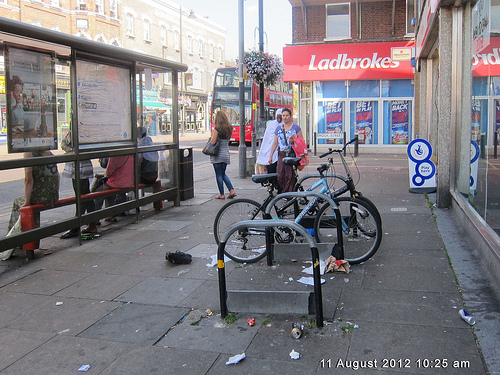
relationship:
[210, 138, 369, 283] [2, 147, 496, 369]
bicycle rack on sidewalk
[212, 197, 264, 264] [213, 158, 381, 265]
wheel on bicycle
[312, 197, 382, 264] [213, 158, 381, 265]
wheel on bicycle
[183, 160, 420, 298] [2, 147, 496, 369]
bicycle on sidewalk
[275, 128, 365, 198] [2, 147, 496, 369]
bicycle on sidewalk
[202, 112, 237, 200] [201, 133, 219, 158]
woman holding bag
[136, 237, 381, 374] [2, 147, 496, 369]
trash on sidewalk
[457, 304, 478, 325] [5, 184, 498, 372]
can on ground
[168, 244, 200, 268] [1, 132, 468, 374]
trash on sidewalk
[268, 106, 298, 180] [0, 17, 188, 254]
people at bus stop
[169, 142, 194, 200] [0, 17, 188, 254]
trash can at bus stop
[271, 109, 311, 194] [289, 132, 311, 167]
woman with sweater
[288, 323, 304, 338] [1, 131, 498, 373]
can on concrete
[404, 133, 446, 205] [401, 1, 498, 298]
sign on building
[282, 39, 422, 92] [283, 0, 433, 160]
awning on store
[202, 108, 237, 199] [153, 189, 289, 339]
woman on sidewalk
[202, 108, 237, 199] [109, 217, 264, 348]
woman walking on sidealk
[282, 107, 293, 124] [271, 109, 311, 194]
head of woman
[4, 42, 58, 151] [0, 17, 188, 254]
advertisement on bus stop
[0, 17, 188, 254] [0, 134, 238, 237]
bus stop next to road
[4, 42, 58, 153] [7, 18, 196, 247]
sign on bus stop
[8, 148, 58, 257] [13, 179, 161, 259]
person sitting on bench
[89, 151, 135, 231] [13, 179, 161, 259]
person sitting on bench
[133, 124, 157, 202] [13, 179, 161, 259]
person sitting on bench